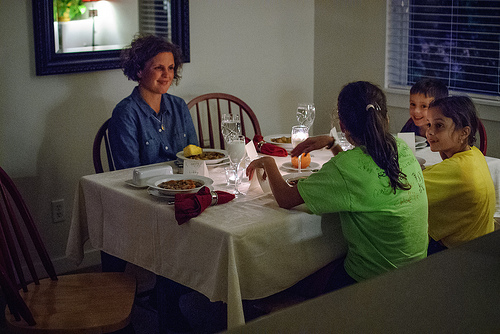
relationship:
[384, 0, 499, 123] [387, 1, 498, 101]
window has blind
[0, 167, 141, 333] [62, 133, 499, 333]
chair away from table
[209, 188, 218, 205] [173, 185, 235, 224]
ring on napkin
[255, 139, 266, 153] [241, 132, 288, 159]
ring on napkin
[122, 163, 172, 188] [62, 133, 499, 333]
butter dish on table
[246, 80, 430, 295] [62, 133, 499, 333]
girl at table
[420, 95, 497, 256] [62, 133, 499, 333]
girl at table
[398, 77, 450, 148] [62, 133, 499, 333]
boy at table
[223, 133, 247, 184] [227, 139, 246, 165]
glass contains milk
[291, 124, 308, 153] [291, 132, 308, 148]
glass contains milk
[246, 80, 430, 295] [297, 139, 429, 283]
girl wearing shirt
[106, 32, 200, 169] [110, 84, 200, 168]
woman wearing shirt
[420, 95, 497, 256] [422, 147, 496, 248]
girl wearing shirt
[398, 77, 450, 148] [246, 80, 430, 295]
boy looking at girl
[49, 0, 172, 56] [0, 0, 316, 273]
mirror on wall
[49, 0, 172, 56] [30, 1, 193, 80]
mirror in frame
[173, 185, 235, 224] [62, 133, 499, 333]
napkin on table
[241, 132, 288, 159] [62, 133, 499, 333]
napkin on table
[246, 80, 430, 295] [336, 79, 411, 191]
girl has hair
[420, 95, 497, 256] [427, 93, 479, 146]
girl has hair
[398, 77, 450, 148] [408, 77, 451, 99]
boy has hair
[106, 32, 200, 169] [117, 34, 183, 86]
woman has hair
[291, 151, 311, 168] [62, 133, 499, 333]
candle on table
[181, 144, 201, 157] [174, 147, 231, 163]
cornbread on plate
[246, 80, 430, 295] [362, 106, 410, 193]
girl has ponytail